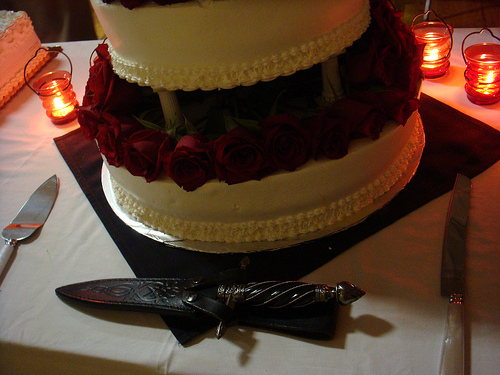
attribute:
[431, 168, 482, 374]
pie cutter — metal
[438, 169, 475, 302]
blade — silver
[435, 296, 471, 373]
handle — white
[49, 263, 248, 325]
sheath — black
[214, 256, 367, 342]
knife handle — black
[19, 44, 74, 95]
candle handle — round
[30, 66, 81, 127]
candle holder — clear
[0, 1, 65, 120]
cake — rectangular, white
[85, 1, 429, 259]
cake — round, large, white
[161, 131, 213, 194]
rose — red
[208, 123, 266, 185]
rose — red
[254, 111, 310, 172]
rose — red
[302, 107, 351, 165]
rose — red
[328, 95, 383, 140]
rose — red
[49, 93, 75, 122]
candle — decorative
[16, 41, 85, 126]
jar — red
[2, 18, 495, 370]
tablecloth — white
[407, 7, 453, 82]
candle — decorative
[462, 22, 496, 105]
candle — decorative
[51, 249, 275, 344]
case — black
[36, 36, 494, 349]
napkin — black